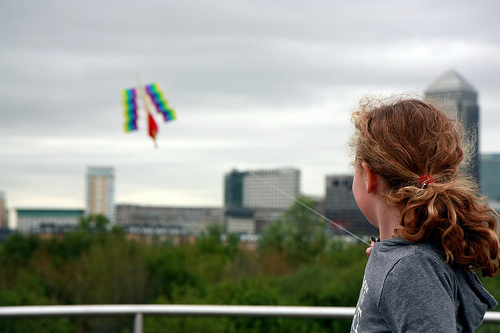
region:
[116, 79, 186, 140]
kite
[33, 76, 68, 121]
white clouds in blule sky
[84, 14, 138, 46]
white clouds in blule sky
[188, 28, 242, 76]
white clouds in blule sky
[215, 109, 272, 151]
white clouds in blule sky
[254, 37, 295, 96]
white clouds in blule sky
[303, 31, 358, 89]
white clouds in blule sky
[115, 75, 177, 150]
A colorful kite flying in the wind.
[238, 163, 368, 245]
The string of a kite.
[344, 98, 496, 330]
A child holding onto a kit's string.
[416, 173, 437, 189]
A red tie holding long hair.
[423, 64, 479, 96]
Roof of a building in the distance.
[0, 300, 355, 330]
A brushed steel railing.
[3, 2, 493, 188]
Gray clouds covering the sky.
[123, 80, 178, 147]
A rainbow color kite in the sky.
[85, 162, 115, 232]
A distant building behind foliage.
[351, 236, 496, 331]
Gray hoodie on a kid.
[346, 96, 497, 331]
redhead little girl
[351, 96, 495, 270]
large red hair of kid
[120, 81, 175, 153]
multicolored kite in sky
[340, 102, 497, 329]
redhead girl flying a kite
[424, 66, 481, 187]
big tall building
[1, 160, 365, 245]
a bunch of small buildings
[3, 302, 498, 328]
gray metal rail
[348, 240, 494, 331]
gray sweater of redhead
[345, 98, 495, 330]
redhead girl wearing gray sweater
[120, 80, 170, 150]
the kite is in the air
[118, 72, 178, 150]
the kite is colorful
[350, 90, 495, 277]
the girl has curly hair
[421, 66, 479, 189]
the building is tall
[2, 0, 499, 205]
the sky is cloudy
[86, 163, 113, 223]
the building is yellow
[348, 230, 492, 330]
the girl wears a gray shirt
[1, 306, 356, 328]
the railing is metal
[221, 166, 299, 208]
the buildings have windows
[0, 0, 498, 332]
the scene takes place outdoors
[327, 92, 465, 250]
head of a person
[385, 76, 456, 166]
hair of a person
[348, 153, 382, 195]
ear of a person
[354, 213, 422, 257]
neck of a person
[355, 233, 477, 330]
body of a person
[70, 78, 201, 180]
kite in mid air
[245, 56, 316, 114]
sky with some clouds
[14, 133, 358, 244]
bunch of buildings in background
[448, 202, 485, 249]
hair of a person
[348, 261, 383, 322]
chest of a person